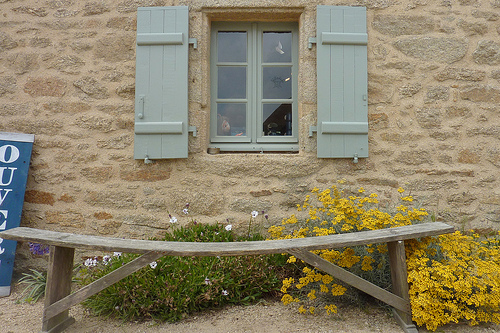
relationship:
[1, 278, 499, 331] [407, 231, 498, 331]
ground has flowers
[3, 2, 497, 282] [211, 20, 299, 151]
house has window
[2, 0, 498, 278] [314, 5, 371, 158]
wall has shutters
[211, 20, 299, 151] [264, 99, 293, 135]
window has shadow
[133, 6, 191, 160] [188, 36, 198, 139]
shutter has hinges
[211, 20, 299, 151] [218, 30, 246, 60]
window has pane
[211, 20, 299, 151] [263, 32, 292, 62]
window has pane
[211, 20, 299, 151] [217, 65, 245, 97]
window has pane